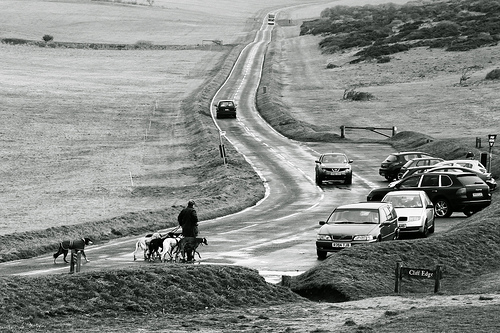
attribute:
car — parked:
[311, 147, 354, 187]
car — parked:
[310, 203, 398, 242]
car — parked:
[359, 167, 491, 215]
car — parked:
[210, 98, 239, 120]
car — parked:
[372, 151, 437, 176]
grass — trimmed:
[2, 1, 242, 226]